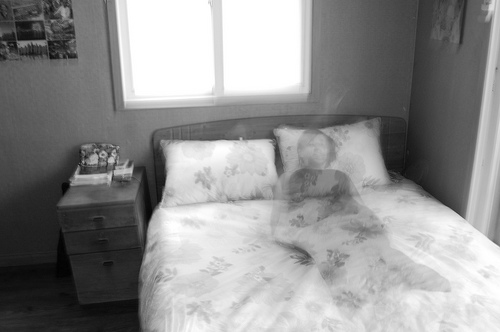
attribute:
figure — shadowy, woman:
[280, 129, 414, 314]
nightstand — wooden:
[60, 168, 146, 317]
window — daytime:
[105, 1, 320, 103]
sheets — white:
[152, 174, 493, 331]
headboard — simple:
[154, 116, 404, 184]